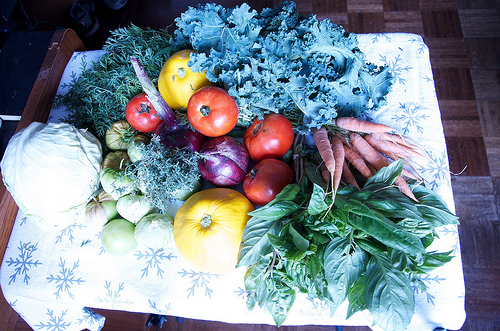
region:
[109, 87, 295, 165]
red tomatoes on the mat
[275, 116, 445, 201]
carrots on the mat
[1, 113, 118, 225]
green cabbage on the mat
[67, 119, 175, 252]
tomatillos on the mat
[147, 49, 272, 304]
yellow squash on the mat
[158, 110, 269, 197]
red onions on the mat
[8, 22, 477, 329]
the mat is white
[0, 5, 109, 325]
mat on a wooden object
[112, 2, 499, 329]
the floor is brown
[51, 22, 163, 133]
green vegetable next to tomato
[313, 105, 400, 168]
bunch of carrots in a bunch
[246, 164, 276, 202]
red ripe tomato on table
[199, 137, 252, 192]
deep purple vegetable on table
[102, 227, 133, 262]
small green vegetables on table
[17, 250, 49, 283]
tablecloth has snow flakes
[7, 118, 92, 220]
green cabbage on end of table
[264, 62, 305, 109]
group of green kale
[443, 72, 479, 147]
brown squares on floor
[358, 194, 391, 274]
medium green leaves of vegetable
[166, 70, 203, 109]
larger orange vegetable on table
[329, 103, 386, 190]
There are orange carrots on the table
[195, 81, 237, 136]
There is a bright white tomato here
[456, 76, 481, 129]
There are brown squares in the floor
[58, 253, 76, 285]
There are snowflakes on the tablecloth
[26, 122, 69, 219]
There is a head of cabbage here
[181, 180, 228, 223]
There is a small squash visible in the photo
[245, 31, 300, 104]
There are bright leafy greens visible here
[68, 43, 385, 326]
Jackson Mingus took this photo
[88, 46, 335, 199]
This photo is owned by Nicholas Zander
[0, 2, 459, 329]
the vegetables on the table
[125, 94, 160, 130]
the tomato on the table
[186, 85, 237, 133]
the tomato on the table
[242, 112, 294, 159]
the tomato on the table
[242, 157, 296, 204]
the tomato on the table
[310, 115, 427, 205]
the carrots in a pile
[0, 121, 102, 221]
the head of cabbage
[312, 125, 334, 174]
the carrot in the pile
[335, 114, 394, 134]
the carrot in the pile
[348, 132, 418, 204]
the carrot in the pile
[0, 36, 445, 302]
a table with vegtables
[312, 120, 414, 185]
orange carrots on a table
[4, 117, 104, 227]
green cabbage on a table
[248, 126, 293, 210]
red tomatoes on a table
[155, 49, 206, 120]
yellow squash on a table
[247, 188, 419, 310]
green spinach on a table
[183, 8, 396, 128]
kale on a table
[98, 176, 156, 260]
onions on a table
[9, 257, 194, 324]
a white cloth on a table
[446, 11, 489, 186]
a tile wooden floor